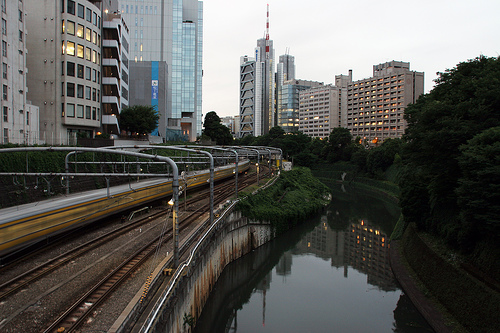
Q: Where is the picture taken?
A: In an urban scene.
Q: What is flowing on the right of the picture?
A: River.